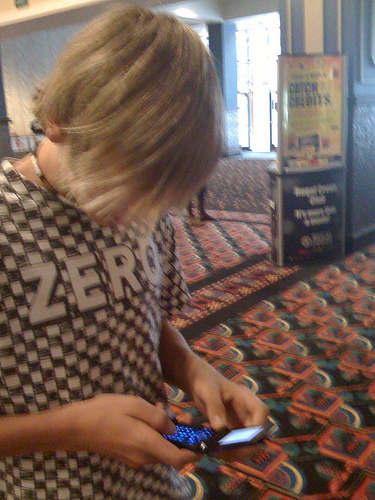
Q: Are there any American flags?
A: No, there are no American flags.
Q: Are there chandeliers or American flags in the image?
A: No, there are no American flags or chandeliers.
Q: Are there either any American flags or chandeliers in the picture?
A: No, there are no American flags or chandeliers.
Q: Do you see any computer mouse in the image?
A: No, there are no computer mice.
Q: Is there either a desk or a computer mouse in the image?
A: No, there are no computer mice or desks.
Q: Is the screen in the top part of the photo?
A: No, the screen is in the bottom of the image.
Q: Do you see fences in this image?
A: No, there are no fences.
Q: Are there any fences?
A: No, there are no fences.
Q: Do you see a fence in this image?
A: No, there are no fences.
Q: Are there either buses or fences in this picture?
A: No, there are no fences or buses.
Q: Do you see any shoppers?
A: No, there are no shoppers.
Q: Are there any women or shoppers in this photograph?
A: No, there are no shoppers or women.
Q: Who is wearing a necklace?
A: The boy is wearing a necklace.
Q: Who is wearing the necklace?
A: The boy is wearing a necklace.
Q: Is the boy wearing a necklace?
A: Yes, the boy is wearing a necklace.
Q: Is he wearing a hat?
A: No, the boy is wearing a necklace.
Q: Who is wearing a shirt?
A: The boy is wearing a shirt.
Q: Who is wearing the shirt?
A: The boy is wearing a shirt.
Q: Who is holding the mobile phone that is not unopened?
A: The boy is holding the cell phone.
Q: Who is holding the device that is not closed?
A: The boy is holding the cell phone.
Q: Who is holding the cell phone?
A: The boy is holding the cell phone.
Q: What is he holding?
A: The boy is holding the cellphone.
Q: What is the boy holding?
A: The boy is holding the cellphone.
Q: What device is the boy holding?
A: The boy is holding the mobile phone.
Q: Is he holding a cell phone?
A: Yes, the boy is holding a cell phone.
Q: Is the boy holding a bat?
A: No, the boy is holding a cell phone.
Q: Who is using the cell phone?
A: The boy is using the cell phone.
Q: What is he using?
A: The boy is using a mobile phone.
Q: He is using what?
A: The boy is using a mobile phone.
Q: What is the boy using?
A: The boy is using a mobile phone.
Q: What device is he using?
A: The boy is using a cell phone.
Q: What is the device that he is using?
A: The device is a cell phone.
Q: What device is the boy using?
A: The boy is using a cell phone.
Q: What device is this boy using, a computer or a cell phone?
A: The boy is using a cell phone.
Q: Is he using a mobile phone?
A: Yes, the boy is using a mobile phone.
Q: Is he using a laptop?
A: No, the boy is using a mobile phone.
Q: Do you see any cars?
A: No, there are no cars.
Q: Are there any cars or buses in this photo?
A: No, there are no cars or buses.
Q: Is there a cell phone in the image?
A: Yes, there is a cell phone.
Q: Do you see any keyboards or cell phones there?
A: Yes, there is a cell phone.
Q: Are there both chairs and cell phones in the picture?
A: No, there is a cell phone but no chairs.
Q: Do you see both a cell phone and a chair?
A: No, there is a cell phone but no chairs.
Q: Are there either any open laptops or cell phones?
A: Yes, there is an open cell phone.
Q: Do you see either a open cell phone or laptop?
A: Yes, there is an open cell phone.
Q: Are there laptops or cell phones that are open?
A: Yes, the cell phone is open.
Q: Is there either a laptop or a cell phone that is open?
A: Yes, the cell phone is open.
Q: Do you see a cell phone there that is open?
A: Yes, there is an open cell phone.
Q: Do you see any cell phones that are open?
A: Yes, there is an open cell phone.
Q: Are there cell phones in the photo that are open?
A: Yes, there is a cell phone that is open.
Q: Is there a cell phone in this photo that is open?
A: Yes, there is a cell phone that is open.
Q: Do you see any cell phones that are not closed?
A: Yes, there is a open cell phone.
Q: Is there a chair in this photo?
A: No, there are no chairs.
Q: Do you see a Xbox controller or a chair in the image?
A: No, there are no chairs or Xbox controllers.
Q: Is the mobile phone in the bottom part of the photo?
A: Yes, the mobile phone is in the bottom of the image.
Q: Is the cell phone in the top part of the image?
A: No, the cell phone is in the bottom of the image.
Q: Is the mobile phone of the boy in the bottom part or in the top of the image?
A: The mobile phone is in the bottom of the image.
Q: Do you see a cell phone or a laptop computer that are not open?
A: No, there is a cell phone but it is open.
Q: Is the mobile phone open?
A: Yes, the mobile phone is open.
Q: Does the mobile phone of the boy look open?
A: Yes, the cellphone is open.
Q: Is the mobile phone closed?
A: No, the mobile phone is open.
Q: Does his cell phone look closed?
A: No, the cellphone is open.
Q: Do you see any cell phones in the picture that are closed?
A: No, there is a cell phone but it is open.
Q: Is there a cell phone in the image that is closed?
A: No, there is a cell phone but it is open.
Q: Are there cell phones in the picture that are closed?
A: No, there is a cell phone but it is open.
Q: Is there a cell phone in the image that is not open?
A: No, there is a cell phone but it is open.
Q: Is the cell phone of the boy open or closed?
A: The cellphone is open.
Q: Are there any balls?
A: No, there are no balls.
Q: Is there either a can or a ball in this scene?
A: No, there are no balls or cans.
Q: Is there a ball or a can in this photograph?
A: No, there are no balls or cans.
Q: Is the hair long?
A: Yes, the hair is long.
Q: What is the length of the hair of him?
A: The hair is long.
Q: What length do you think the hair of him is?
A: The hair is long.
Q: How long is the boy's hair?
A: The hair is long.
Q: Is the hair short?
A: No, the hair is long.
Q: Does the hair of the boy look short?
A: No, the hair is long.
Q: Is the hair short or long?
A: The hair is long.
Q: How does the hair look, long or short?
A: The hair is long.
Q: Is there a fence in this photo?
A: No, there are no fences.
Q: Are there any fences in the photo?
A: No, there are no fences.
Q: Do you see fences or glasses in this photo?
A: No, there are no fences or glasses.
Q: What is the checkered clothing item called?
A: The clothing item is a shirt.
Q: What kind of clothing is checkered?
A: The clothing is a shirt.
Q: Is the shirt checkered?
A: Yes, the shirt is checkered.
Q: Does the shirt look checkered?
A: Yes, the shirt is checkered.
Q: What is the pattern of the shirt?
A: The shirt is checkered.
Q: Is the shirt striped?
A: No, the shirt is checkered.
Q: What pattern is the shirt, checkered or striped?
A: The shirt is checkered.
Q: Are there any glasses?
A: No, there are no glasses.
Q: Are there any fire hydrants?
A: No, there are no fire hydrants.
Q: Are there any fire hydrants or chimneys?
A: No, there are no fire hydrants or chimneys.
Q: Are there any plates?
A: No, there are no plates.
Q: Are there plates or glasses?
A: No, there are no plates or glasses.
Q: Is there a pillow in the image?
A: No, there are no pillows.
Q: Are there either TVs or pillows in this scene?
A: No, there are no pillows or tvs.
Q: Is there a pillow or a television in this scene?
A: No, there are no pillows or televisions.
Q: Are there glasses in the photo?
A: No, there are no glasses.